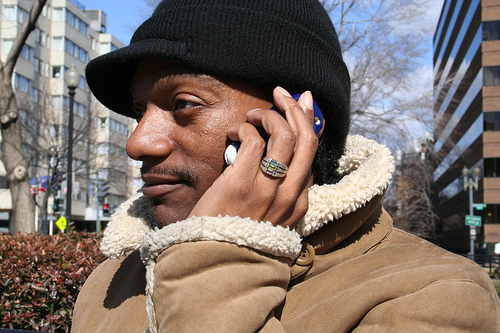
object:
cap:
[84, 0, 351, 154]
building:
[421, 0, 499, 263]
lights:
[97, 180, 111, 204]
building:
[0, 1, 142, 219]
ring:
[259, 158, 288, 178]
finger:
[275, 82, 318, 198]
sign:
[55, 215, 71, 235]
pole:
[63, 92, 76, 235]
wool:
[191, 219, 254, 239]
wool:
[107, 221, 137, 248]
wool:
[352, 145, 387, 185]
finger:
[225, 121, 265, 187]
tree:
[0, 3, 47, 233]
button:
[292, 241, 318, 267]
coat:
[73, 134, 498, 330]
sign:
[462, 214, 485, 226]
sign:
[467, 201, 488, 211]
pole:
[460, 159, 483, 256]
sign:
[468, 228, 477, 238]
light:
[462, 165, 470, 174]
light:
[472, 165, 482, 175]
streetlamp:
[62, 67, 82, 227]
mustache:
[139, 167, 199, 184]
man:
[72, 0, 500, 333]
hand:
[185, 86, 320, 236]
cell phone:
[219, 94, 327, 167]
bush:
[6, 235, 64, 328]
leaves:
[42, 245, 50, 257]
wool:
[313, 185, 351, 214]